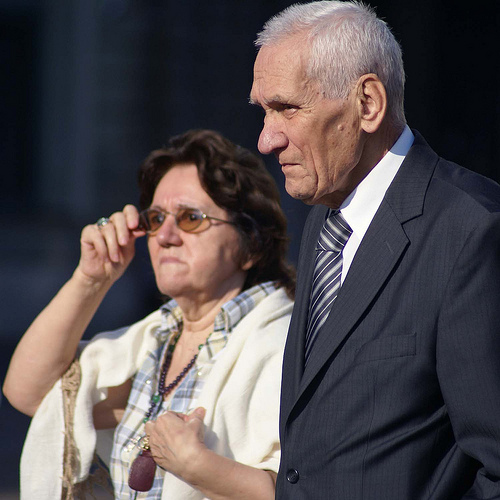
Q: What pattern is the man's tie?
A: Striped.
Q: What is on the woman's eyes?
A: Her glasses.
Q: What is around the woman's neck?
A: A necklace.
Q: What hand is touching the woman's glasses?
A: Her right hand.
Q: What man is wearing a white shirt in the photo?
A: Man wearing blue and white tie.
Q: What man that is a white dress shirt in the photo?
A: Tall man with woman.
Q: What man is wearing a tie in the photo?
A: Man with grey hair.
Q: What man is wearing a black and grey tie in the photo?
A: Man in navy suit.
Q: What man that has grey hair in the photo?
A: Tall man with woman.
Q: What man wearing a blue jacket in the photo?
A: Man with woman in glasses.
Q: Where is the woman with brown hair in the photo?
A: Woman in glasses.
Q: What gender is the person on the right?
A: Male.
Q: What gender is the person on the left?
A: Female.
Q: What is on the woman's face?
A: Glasses.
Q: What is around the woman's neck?
A: Necklace.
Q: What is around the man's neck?
A: Tie.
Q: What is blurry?
A: The background.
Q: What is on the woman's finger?
A: Ring.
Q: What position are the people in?
A: Standing.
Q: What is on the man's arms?
A: Jacket.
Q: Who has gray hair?
A: The man on the right.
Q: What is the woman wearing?
A: Shawl.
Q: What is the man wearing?
A: Suit.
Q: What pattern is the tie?
A: Striped.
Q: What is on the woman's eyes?
A: Glasses.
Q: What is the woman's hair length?
A: Short.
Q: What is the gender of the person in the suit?
A: Male.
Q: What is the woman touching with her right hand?
A: Eye glasses.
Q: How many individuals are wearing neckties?
A: One.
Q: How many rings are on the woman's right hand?
A: One.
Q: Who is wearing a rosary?
A: The woman.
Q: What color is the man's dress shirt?
A: White.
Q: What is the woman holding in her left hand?
A: A key ring.